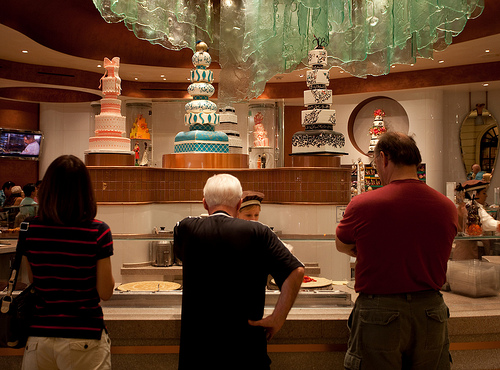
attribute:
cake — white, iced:
[170, 37, 226, 153]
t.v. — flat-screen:
[4, 121, 48, 162]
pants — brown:
[343, 292, 453, 368]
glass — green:
[217, 4, 461, 79]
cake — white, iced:
[291, 43, 345, 159]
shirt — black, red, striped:
[35, 220, 99, 335]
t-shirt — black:
[164, 206, 306, 365]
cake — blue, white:
[165, 33, 230, 168]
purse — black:
[0, 217, 32, 349]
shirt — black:
[121, 217, 308, 311]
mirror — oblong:
[96, 0, 480, 111]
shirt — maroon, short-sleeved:
[330, 178, 462, 301]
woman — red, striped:
[11, 153, 139, 368]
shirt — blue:
[8, 211, 118, 340]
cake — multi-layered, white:
[293, 46, 355, 154]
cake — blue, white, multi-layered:
[171, 39, 231, 152]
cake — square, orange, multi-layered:
[66, 41, 163, 181]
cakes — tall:
[87, 37, 346, 164]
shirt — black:
[170, 210, 302, 364]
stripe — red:
[95, 225, 109, 243]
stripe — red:
[22, 221, 100, 233]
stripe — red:
[19, 235, 99, 247]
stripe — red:
[25, 248, 102, 259]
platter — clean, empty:
[115, 280, 181, 290]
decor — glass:
[93, 0, 488, 75]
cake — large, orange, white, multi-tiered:
[81, 50, 143, 185]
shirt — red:
[334, 177, 459, 292]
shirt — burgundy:
[333, 186, 465, 300]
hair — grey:
[201, 166, 244, 206]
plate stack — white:
[448, 255, 497, 298]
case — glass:
[128, 99, 155, 168]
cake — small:
[126, 108, 151, 142]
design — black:
[303, 81, 334, 105]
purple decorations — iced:
[180, 110, 217, 125]